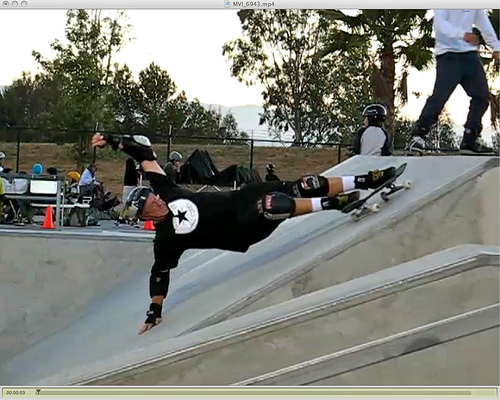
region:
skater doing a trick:
[73, 108, 410, 324]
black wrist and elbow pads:
[110, 256, 204, 338]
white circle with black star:
[161, 189, 218, 248]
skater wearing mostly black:
[71, 119, 348, 294]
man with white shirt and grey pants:
[394, 19, 488, 165]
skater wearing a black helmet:
[338, 97, 406, 181]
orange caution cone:
[34, 192, 79, 230]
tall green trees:
[211, 12, 422, 159]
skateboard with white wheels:
[330, 164, 437, 247]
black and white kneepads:
[242, 161, 348, 254]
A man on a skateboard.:
[82, 114, 426, 342]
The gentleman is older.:
[73, 115, 433, 344]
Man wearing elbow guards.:
[113, 121, 201, 316]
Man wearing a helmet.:
[115, 169, 199, 242]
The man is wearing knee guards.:
[245, 167, 350, 241]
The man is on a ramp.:
[44, 122, 496, 357]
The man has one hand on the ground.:
[74, 126, 424, 336]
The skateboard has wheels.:
[325, 154, 423, 231]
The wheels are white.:
[341, 157, 431, 237]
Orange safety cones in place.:
[38, 196, 166, 241]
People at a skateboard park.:
[23, 31, 480, 371]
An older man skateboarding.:
[76, 112, 416, 315]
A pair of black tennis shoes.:
[321, 152, 418, 224]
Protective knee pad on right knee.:
[249, 186, 312, 232]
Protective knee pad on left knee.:
[293, 172, 332, 199]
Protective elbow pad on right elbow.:
[135, 260, 176, 300]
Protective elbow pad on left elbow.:
[115, 126, 154, 166]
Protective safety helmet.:
[109, 180, 185, 238]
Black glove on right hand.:
[138, 282, 185, 339]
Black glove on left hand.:
[83, 124, 116, 161]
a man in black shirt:
[132, 153, 303, 298]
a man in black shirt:
[127, 175, 332, 387]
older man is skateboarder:
[133, 186, 194, 217]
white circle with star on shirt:
[170, 190, 205, 239]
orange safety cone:
[15, 205, 69, 242]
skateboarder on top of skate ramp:
[414, 57, 495, 159]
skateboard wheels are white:
[349, 162, 428, 217]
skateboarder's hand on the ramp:
[120, 299, 204, 341]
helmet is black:
[357, 95, 401, 116]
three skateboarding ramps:
[352, 192, 498, 377]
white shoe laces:
[404, 131, 439, 146]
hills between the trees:
[191, 75, 321, 142]